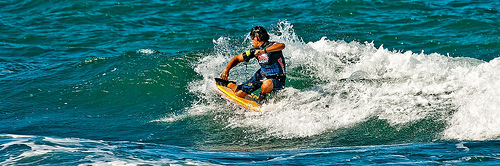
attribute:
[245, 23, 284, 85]
man — wake boarding, surfing, wet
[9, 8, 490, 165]
ocean — blue, deep, clear blue green, blue green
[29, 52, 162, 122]
waves — green, white, nice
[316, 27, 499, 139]
water — white, blue, green, choppy, blue-green, turbulent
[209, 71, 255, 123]
surfboard — yellow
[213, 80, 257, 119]
board — yellow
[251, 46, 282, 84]
wetsuit — black, blue, lime green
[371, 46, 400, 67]
cap — white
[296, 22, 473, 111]
wave — white, breaking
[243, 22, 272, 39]
hair — dark, short, wet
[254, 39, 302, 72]
arm — in air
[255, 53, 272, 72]
advertisements — printed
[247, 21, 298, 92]
person — surfing